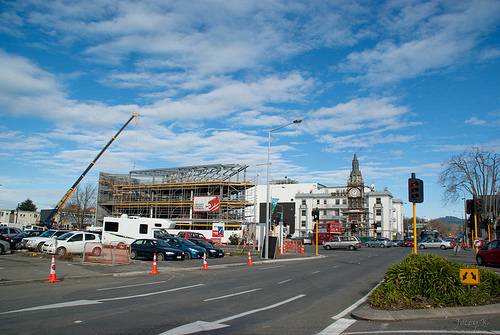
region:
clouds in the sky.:
[165, 18, 217, 31]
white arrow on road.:
[182, 315, 219, 334]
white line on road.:
[208, 281, 264, 304]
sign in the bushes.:
[456, 269, 479, 286]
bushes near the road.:
[392, 270, 434, 295]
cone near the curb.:
[47, 255, 61, 281]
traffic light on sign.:
[402, 174, 422, 206]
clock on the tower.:
[345, 187, 361, 197]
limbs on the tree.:
[450, 156, 482, 191]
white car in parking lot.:
[62, 233, 81, 250]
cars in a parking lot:
[22, 227, 102, 257]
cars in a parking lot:
[128, 228, 228, 265]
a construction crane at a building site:
[22, 107, 145, 229]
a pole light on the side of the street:
[255, 116, 307, 261]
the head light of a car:
[163, 247, 175, 257]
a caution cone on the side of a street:
[44, 253, 64, 287]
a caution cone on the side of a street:
[147, 252, 162, 277]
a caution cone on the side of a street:
[196, 252, 211, 274]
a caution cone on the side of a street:
[242, 247, 256, 271]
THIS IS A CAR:
[39, 215, 95, 265]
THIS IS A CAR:
[14, 221, 65, 246]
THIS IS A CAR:
[128, 229, 192, 286]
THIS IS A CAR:
[162, 223, 217, 277]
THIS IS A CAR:
[177, 221, 226, 270]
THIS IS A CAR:
[309, 223, 369, 265]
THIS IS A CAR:
[365, 220, 402, 252]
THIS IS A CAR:
[408, 225, 460, 263]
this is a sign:
[146, 248, 178, 293]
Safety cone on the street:
[43, 248, 65, 284]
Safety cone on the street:
[148, 248, 167, 279]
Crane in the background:
[43, 101, 144, 218]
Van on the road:
[321, 230, 366, 259]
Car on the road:
[411, 231, 453, 255]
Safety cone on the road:
[193, 251, 215, 271]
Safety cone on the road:
[239, 247, 261, 269]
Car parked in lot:
[126, 231, 183, 261]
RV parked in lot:
[94, 212, 171, 244]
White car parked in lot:
[42, 227, 101, 259]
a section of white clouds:
[303, 95, 419, 130]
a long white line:
[195, 284, 267, 306]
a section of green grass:
[368, 249, 498, 309]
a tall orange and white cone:
[45, 253, 63, 283]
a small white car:
[42, 227, 104, 258]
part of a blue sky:
[416, 81, 480, 114]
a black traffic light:
[406, 177, 421, 204]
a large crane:
[50, 105, 142, 226]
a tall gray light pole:
[263, 116, 305, 260]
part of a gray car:
[417, 236, 452, 249]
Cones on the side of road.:
[34, 250, 287, 273]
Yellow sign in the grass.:
[458, 268, 475, 289]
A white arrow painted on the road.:
[172, 305, 307, 327]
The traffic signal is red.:
[400, 173, 424, 201]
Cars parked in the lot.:
[9, 225, 197, 262]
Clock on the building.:
[340, 178, 366, 199]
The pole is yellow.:
[405, 205, 426, 252]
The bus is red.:
[308, 218, 338, 243]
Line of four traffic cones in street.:
[35, 250, 260, 285]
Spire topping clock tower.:
[335, 155, 368, 198]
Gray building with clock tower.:
[341, 153, 368, 238]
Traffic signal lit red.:
[403, 170, 425, 203]